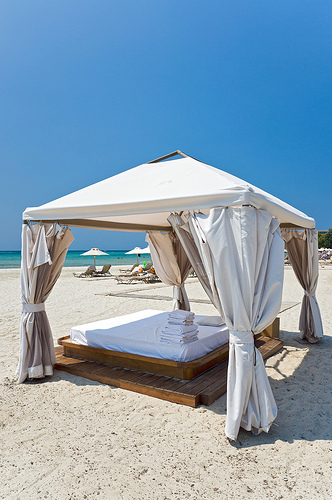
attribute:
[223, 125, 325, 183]
clouds — white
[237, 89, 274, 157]
clouds — white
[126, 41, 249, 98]
clouds — white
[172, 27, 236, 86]
sky — blue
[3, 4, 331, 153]
sky — blue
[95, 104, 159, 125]
cloud — white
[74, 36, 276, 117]
sky — blue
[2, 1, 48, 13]
clouds — white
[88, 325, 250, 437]
platform — wooden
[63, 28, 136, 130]
clouds — white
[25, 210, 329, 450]
curtains — tied-back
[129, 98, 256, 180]
clouds — white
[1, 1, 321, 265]
sky — blue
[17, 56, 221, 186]
clouds — white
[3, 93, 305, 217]
clouds — white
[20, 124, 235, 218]
clouds — white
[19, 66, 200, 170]
clouds — white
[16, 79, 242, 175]
clouds — white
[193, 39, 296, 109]
clouds — white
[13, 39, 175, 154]
clouds — white